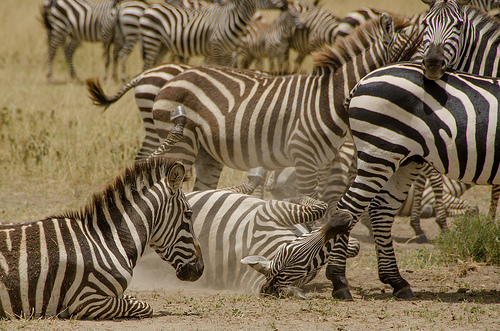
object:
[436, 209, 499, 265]
grass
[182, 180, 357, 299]
zebra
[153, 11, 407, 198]
zebra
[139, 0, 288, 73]
zebra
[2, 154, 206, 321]
zebra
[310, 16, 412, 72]
mane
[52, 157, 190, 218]
mane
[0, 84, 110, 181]
grass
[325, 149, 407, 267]
leg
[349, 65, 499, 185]
stripes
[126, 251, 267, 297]
dust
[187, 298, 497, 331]
ground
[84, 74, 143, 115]
moving tail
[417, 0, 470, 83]
zebra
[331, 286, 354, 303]
edge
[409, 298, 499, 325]
part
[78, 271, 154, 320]
part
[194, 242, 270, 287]
back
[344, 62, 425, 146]
hindquarter